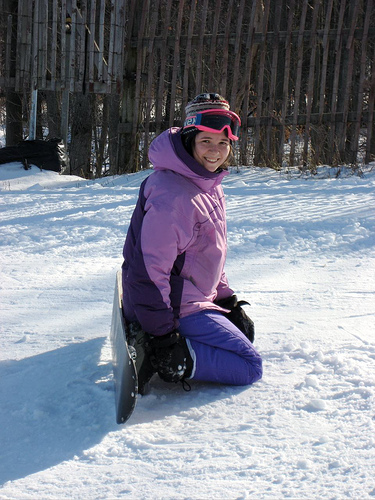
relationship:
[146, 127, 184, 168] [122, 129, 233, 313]
hood on jacket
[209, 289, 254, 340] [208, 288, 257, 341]
glove on hand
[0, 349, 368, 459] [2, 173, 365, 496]
tracks in snow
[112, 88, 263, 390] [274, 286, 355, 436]
girl kneeling in snow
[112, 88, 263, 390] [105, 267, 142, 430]
girl with snowboard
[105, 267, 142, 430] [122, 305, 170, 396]
snowboard on feet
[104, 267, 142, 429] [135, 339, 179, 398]
snowboard attached to feet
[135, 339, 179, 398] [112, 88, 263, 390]
feet of girl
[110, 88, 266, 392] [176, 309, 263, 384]
girl dressed in pants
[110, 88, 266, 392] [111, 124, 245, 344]
girl dressed in jacket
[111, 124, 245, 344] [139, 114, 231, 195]
jacket with hood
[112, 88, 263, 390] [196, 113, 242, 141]
girl wearing eyewear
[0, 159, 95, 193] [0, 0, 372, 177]
snow piled up against fence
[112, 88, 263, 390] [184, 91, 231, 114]
girl wearing cap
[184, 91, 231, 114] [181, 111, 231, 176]
cap on head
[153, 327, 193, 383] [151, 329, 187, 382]
glove on hand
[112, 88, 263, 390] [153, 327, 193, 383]
girl wearing a glove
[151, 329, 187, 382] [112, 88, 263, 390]
hand of girl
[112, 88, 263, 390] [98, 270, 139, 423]
girl on snowboard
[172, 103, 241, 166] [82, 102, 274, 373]
face on girl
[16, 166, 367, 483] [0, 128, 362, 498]
snow covering field